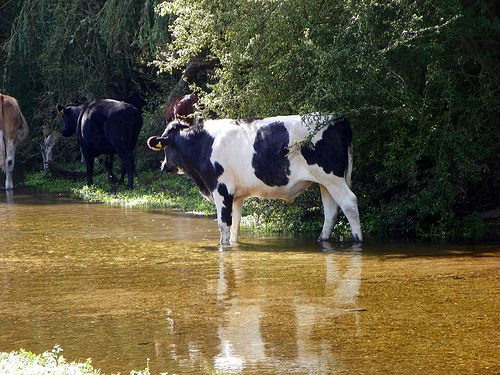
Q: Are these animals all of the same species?
A: No, there are both cows and bulls.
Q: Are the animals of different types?
A: Yes, they are cows and bulls.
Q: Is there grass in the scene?
A: Yes, there is grass.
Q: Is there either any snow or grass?
A: Yes, there is grass.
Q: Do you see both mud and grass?
A: No, there is grass but no mud.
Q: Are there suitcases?
A: No, there are no suitcases.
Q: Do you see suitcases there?
A: No, there are no suitcases.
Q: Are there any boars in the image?
A: No, there are no boars.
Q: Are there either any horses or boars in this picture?
A: No, there are no boars or horses.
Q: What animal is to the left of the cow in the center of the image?
A: The animal is a bull.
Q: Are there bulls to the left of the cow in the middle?
A: Yes, there is a bull to the left of the cow.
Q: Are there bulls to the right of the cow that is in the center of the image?
A: No, the bull is to the left of the cow.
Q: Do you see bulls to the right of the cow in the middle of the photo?
A: No, the bull is to the left of the cow.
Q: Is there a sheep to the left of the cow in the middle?
A: No, there is a bull to the left of the cow.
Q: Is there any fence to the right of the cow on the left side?
A: No, there is a bull to the right of the cow.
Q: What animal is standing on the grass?
A: The bull is standing on the grass.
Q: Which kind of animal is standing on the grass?
A: The animal is a bull.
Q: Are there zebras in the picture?
A: No, there are no zebras.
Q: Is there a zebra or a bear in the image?
A: No, there are no zebras or bears.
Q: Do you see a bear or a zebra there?
A: No, there are no zebras or bears.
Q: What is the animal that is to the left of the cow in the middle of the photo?
A: The animal is a bull.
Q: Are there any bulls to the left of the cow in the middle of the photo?
A: Yes, there is a bull to the left of the cow.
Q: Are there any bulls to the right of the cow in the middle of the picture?
A: No, the bull is to the left of the cow.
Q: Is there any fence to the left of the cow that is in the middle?
A: No, there is a bull to the left of the cow.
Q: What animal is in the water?
A: The bull is in the water.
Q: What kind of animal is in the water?
A: The animal is a bull.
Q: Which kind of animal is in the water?
A: The animal is a bull.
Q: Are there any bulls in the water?
A: Yes, there is a bull in the water.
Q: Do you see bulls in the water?
A: Yes, there is a bull in the water.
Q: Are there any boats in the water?
A: No, there is a bull in the water.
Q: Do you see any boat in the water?
A: No, there is a bull in the water.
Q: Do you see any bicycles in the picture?
A: No, there are no bicycles.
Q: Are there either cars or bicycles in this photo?
A: No, there are no bicycles or cars.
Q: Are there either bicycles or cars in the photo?
A: No, there are no bicycles or cars.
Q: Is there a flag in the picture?
A: No, there are no flags.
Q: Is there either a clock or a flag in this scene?
A: No, there are no flags or clocks.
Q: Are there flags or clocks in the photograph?
A: No, there are no flags or clocks.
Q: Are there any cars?
A: No, there are no cars.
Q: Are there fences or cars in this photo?
A: No, there are no cars or fences.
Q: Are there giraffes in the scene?
A: No, there are no giraffes.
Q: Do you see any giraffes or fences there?
A: No, there are no giraffes or fences.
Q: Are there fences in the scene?
A: No, there are no fences.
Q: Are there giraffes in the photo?
A: No, there are no giraffes.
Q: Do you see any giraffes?
A: No, there are no giraffes.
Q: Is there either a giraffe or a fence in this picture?
A: No, there are no giraffes or fences.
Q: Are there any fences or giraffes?
A: No, there are no giraffes or fences.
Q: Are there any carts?
A: No, there are no carts.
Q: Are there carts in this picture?
A: No, there are no carts.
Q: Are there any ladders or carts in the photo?
A: No, there are no carts or ladders.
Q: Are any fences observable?
A: No, there are no fences.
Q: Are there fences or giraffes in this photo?
A: No, there are no fences or giraffes.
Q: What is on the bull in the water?
A: The spots are on the bull.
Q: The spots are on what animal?
A: The spots are on the bull.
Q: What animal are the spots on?
A: The spots are on the bull.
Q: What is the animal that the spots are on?
A: The animal is a bull.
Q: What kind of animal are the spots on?
A: The spots are on the bull.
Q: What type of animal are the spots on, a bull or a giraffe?
A: The spots are on a bull.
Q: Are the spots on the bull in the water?
A: Yes, the spots are on the bull.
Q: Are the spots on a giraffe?
A: No, the spots are on the bull.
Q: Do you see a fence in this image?
A: No, there are no fences.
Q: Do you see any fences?
A: No, there are no fences.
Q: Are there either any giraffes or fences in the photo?
A: No, there are no fences or giraffes.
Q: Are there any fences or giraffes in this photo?
A: No, there are no fences or giraffes.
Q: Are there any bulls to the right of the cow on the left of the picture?
A: Yes, there is a bull to the right of the cow.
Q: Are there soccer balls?
A: No, there are no soccer balls.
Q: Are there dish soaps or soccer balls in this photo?
A: No, there are no soccer balls or dish soaps.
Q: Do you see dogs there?
A: No, there are no dogs.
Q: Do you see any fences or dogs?
A: No, there are no dogs or fences.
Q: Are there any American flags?
A: No, there are no American flags.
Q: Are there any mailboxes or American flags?
A: No, there are no American flags or mailboxes.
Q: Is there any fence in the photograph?
A: No, there are no fences.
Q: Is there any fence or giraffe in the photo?
A: No, there are no fences or giraffes.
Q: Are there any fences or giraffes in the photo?
A: No, there are no fences or giraffes.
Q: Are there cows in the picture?
A: Yes, there is a cow.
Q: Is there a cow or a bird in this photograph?
A: Yes, there is a cow.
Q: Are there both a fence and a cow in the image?
A: No, there is a cow but no fences.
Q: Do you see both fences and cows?
A: No, there is a cow but no fences.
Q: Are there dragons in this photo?
A: No, there are no dragons.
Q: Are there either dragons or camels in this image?
A: No, there are no dragons or camels.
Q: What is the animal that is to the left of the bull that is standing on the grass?
A: The animal is a cow.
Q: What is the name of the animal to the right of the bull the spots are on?
A: The animal is a cow.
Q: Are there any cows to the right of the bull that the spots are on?
A: Yes, there is a cow to the right of the bull.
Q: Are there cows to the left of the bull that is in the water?
A: No, the cow is to the right of the bull.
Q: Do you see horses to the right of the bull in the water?
A: No, there is a cow to the right of the bull.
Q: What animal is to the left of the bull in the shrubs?
A: The animal is a cow.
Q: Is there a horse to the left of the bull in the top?
A: No, there is a cow to the left of the bull.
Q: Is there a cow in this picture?
A: Yes, there is a cow.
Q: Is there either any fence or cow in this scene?
A: Yes, there is a cow.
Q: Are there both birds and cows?
A: No, there is a cow but no birds.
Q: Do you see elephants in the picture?
A: No, there are no elephants.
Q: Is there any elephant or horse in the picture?
A: No, there are no elephants or horses.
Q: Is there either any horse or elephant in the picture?
A: No, there are no elephants or horses.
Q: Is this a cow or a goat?
A: This is a cow.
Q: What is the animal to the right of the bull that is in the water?
A: The animal is a cow.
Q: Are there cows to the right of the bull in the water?
A: Yes, there is a cow to the right of the bull.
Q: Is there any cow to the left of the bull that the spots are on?
A: No, the cow is to the right of the bull.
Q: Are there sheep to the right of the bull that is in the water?
A: No, there is a cow to the right of the bull.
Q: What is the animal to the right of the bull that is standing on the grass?
A: The animal is a cow.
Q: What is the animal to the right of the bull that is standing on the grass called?
A: The animal is a cow.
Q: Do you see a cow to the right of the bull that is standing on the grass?
A: Yes, there is a cow to the right of the bull.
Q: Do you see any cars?
A: No, there are no cars.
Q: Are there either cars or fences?
A: No, there are no cars or fences.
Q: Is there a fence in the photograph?
A: No, there are no fences.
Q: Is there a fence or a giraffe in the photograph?
A: No, there are no fences or giraffes.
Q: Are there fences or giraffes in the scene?
A: No, there are no fences or giraffes.